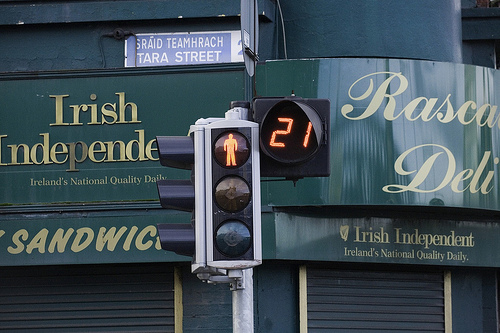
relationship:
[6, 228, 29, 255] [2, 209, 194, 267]
letter on sign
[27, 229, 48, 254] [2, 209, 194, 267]
letter on sign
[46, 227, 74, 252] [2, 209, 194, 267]
letter on sign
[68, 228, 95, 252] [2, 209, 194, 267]
letter on sign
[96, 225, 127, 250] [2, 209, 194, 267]
letter on sign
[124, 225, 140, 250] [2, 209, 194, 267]
letter on sign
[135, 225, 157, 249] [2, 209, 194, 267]
letter on sign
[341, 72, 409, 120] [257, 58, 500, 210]
letter on sign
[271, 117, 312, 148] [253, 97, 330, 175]
number on sign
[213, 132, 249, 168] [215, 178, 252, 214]
light on top of light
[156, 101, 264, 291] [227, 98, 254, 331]
traffic light on pole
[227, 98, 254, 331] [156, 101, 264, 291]
pole with traffic light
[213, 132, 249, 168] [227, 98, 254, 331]
light on pole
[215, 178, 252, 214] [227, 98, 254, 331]
light on pole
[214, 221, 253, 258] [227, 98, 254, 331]
light on pole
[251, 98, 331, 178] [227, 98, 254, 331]
timer on pole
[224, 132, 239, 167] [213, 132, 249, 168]
man on light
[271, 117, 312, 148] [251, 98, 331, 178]
number on timer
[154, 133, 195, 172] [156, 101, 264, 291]
cover on traffic light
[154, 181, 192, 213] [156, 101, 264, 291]
cover on traffic light